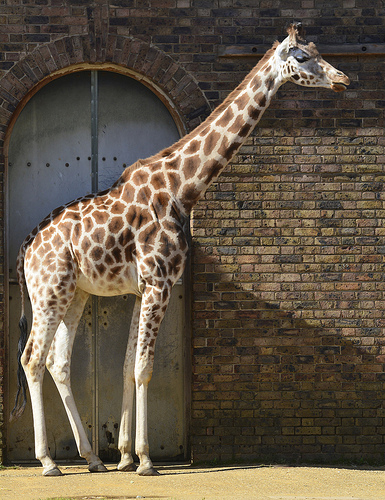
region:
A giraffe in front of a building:
[2, 6, 360, 482]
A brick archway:
[0, 8, 211, 113]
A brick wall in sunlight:
[259, 136, 377, 287]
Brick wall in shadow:
[206, 323, 297, 456]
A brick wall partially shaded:
[218, 210, 336, 420]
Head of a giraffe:
[255, 11, 356, 104]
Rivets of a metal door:
[8, 135, 87, 182]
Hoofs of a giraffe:
[22, 441, 174, 481]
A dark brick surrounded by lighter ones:
[262, 246, 313, 272]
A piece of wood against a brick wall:
[334, 36, 382, 61]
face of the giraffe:
[255, 34, 361, 104]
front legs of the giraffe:
[119, 408, 183, 482]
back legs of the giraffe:
[17, 385, 118, 497]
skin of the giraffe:
[223, 109, 246, 127]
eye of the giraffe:
[279, 46, 316, 68]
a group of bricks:
[211, 389, 382, 465]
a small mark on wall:
[158, 436, 191, 460]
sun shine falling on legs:
[11, 303, 166, 421]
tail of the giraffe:
[9, 281, 40, 436]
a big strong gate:
[34, 44, 225, 491]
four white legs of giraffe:
[11, 220, 199, 484]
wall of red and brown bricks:
[211, 239, 373, 463]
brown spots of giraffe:
[25, 175, 197, 334]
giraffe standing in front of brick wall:
[9, 9, 362, 283]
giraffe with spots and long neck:
[13, 7, 359, 330]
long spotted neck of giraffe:
[155, 4, 360, 258]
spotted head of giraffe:
[249, 13, 354, 124]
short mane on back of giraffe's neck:
[104, 34, 280, 197]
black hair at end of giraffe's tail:
[12, 241, 52, 427]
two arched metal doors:
[3, 45, 196, 461]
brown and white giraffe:
[18, 23, 348, 475]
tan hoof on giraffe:
[89, 462, 106, 472]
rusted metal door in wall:
[7, 70, 186, 463]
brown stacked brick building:
[0, 1, 383, 469]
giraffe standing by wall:
[15, 21, 351, 476]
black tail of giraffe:
[13, 315, 27, 421]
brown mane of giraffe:
[120, 42, 281, 187]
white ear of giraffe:
[276, 44, 285, 58]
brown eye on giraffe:
[295, 55, 309, 62]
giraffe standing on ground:
[16, 21, 349, 474]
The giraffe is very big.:
[9, 24, 358, 480]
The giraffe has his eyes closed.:
[233, 17, 360, 105]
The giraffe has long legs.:
[19, 276, 204, 499]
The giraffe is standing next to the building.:
[1, 8, 365, 481]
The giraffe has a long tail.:
[7, 247, 30, 421]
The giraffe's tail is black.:
[11, 287, 26, 430]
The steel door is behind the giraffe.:
[8, 56, 184, 476]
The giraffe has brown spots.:
[58, 210, 161, 278]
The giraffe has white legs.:
[21, 365, 189, 480]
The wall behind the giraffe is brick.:
[203, 187, 366, 312]